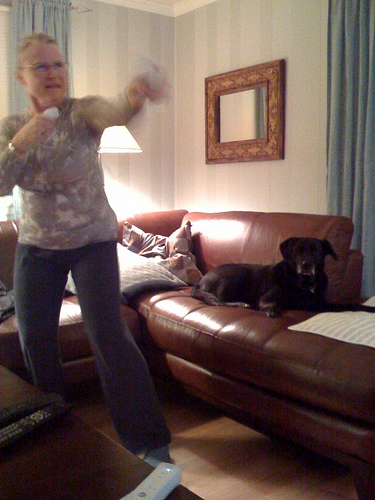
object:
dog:
[193, 233, 334, 323]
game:
[35, 59, 165, 142]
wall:
[190, 33, 278, 52]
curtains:
[2, 2, 19, 119]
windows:
[327, 8, 363, 254]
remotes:
[18, 63, 161, 124]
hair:
[12, 29, 59, 72]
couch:
[1, 207, 363, 498]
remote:
[1, 398, 74, 451]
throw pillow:
[64, 242, 188, 306]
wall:
[175, 1, 198, 150]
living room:
[1, 1, 363, 497]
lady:
[0, 30, 174, 468]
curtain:
[323, 0, 375, 302]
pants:
[12, 238, 172, 453]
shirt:
[0, 96, 143, 250]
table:
[1, 366, 204, 498]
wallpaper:
[71, 1, 125, 89]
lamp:
[96, 124, 142, 185]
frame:
[203, 57, 286, 165]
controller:
[110, 458, 191, 498]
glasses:
[18, 55, 69, 77]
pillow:
[115, 217, 209, 286]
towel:
[297, 308, 373, 357]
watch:
[6, 139, 28, 160]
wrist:
[6, 127, 30, 163]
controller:
[132, 53, 174, 104]